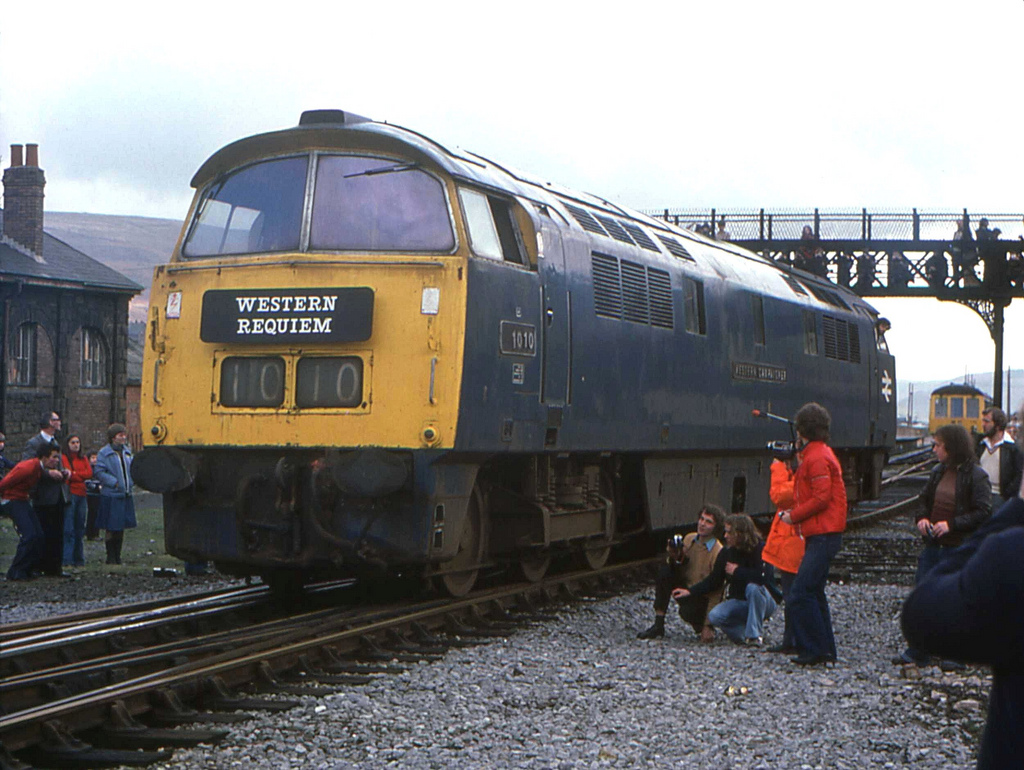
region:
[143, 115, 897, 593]
yellow and black train engine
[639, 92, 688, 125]
white clouds in blue sky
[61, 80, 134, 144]
white clouds in blue sky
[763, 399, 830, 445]
the head of a woman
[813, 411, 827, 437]
the hair of a woman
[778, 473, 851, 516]
the arm of a woman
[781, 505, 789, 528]
the hand of a woman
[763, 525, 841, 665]
the legs of a woman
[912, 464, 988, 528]
the brown shirt of a woman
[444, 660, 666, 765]
gravel that is grey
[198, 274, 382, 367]
the logo of a train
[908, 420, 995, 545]
woman in a black leather jacket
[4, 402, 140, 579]
four people looking at a train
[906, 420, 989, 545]
woman holding a camera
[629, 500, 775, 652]
two people squatting on the ground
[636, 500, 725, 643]
man holding a camera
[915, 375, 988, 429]
yellow and black train behind another train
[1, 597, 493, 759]
brown metal railroad tracks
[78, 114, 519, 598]
front of the train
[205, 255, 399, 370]
words on the train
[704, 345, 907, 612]
person wearing orange colors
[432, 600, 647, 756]
rocks next to the train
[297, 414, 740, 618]
bottom of the train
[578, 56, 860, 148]
sky above the train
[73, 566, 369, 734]
track under the train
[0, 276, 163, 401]
windows on the building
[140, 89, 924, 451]
black and yellow train engine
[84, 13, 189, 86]
white clouds in blue sky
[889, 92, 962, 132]
white clouds in blue sky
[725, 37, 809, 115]
white clouds in blue sky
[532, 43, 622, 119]
white clouds in blue sky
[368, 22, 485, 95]
white clouds in blue sky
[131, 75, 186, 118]
white clouds in blue sky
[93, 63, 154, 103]
white clouds in blue sky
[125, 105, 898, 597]
train is on the track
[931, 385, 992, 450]
train is behind the train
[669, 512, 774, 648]
person is stooped down to the ground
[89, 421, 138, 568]
person is watching the train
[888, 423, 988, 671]
lady is watching the train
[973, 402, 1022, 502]
man is standing on the gravel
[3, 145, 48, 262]
chimney is apart of the building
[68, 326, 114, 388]
window is apart of the building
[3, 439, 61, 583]
man is bending down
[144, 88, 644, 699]
The train has a yellow front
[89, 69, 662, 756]
The train is on the tracks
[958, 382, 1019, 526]
The man is wearing a white shirt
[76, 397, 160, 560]
The woman is wearing a blue coat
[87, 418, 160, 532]
The woman is wearing a blue skirt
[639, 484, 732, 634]
The man is crouching down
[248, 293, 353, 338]
The letters are white